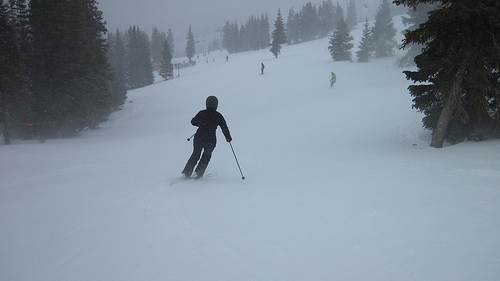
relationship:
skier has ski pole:
[190, 83, 248, 192] [224, 134, 256, 175]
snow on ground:
[139, 65, 400, 227] [57, 164, 373, 278]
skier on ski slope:
[190, 83, 248, 192] [143, 20, 375, 241]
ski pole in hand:
[224, 134, 256, 175] [224, 133, 236, 144]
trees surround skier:
[38, 31, 213, 105] [190, 83, 248, 192]